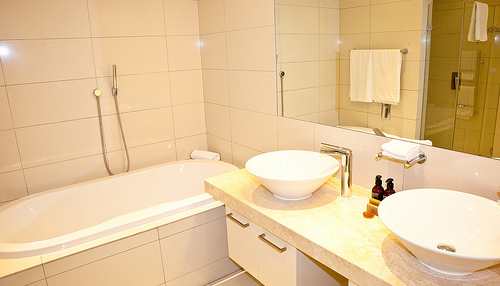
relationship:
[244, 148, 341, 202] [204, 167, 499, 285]
sink on counter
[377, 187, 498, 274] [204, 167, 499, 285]
sink on counter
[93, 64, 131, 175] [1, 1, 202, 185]
hose on wall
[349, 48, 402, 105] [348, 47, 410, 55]
towel on bar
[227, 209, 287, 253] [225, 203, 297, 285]
handles on drawer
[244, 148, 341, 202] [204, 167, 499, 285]
sink above counter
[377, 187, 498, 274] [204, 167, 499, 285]
sink above counter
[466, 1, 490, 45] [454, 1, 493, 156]
towel hanging from door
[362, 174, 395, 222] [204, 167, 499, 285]
toiletries on counter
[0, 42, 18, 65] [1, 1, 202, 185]
light reflected on wall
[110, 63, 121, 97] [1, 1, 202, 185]
shower head on wall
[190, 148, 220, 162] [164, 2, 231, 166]
towel in corner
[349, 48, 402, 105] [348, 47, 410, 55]
towel hanging on bar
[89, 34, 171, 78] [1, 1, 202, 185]
tile on wall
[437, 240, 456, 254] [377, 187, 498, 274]
drain in sink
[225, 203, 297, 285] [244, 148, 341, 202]
drawer under sink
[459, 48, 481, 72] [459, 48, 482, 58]
cloth on holder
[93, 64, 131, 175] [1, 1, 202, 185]
hose attached to wall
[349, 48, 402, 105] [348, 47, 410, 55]
towel hanging from bar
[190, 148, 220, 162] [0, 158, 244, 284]
towel on tub